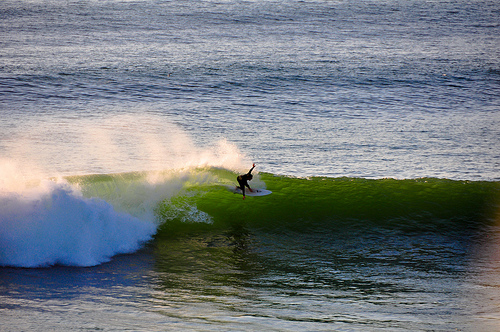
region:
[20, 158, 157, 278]
the wave is large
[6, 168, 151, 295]
the wave is white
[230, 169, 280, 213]
the person is surfing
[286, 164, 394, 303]
the water is green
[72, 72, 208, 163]
the waves are white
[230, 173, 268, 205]
the board is white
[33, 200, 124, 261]
the water is white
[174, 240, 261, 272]
a shadow in the water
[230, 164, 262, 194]
a person surfing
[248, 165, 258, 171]
the persons arm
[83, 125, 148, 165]
a splash of water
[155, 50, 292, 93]
the ocean water is blue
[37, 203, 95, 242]
the water is white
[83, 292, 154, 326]
the water is dark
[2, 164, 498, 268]
large ocean wave curl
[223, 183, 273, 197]
white pointy long board surf board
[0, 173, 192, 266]
white foam of a crashing wave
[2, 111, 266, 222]
water mist from the surf boards wake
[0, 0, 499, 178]
calm blue ocean waters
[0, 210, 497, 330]
calm blue ocean waters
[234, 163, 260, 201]
surf boarder riding a wave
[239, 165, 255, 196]
black surf board style wet suit shirt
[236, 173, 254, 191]
black surf board style wet suit pants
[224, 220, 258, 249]
surfers shadow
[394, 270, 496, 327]
Section of the ocean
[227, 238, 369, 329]
Section of the ocean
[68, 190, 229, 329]
Section of the ocean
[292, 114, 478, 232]
Section of the ocean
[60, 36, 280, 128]
Section of the ocean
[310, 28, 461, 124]
Section of the ocean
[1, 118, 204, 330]
Section of the ocean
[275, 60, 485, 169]
Section of the ocean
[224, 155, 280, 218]
This is a person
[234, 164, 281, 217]
the person is surfing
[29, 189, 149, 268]
the wave is large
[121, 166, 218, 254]
the wave is white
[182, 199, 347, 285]
the water is green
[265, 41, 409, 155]
the water is calm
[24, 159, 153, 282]
the wave is white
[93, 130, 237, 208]
the wave is small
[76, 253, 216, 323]
the water is calm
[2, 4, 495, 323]
the ocean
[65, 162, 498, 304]
the green tint of water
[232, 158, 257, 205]
the surfer in water